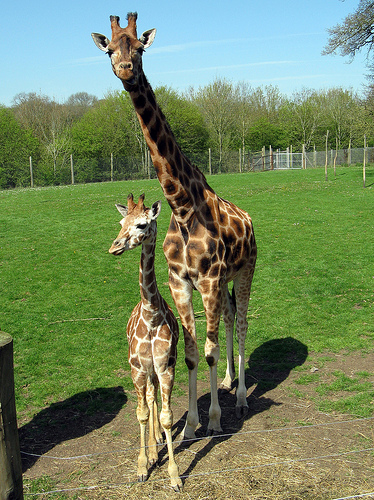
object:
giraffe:
[90, 11, 257, 446]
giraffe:
[108, 193, 178, 496]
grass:
[0, 188, 374, 499]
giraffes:
[90, 8, 258, 494]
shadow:
[149, 336, 308, 485]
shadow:
[15, 385, 127, 473]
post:
[29, 156, 34, 188]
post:
[70, 154, 75, 184]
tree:
[0, 106, 43, 189]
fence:
[29, 129, 374, 188]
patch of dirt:
[0, 336, 374, 500]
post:
[111, 151, 114, 181]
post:
[148, 150, 152, 179]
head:
[91, 10, 156, 87]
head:
[108, 192, 161, 256]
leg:
[235, 285, 250, 398]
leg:
[221, 292, 237, 381]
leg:
[168, 286, 200, 412]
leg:
[204, 295, 221, 422]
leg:
[146, 385, 157, 450]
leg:
[136, 380, 150, 465]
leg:
[159, 375, 178, 479]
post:
[209, 148, 213, 175]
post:
[239, 147, 242, 173]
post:
[287, 147, 290, 168]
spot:
[133, 95, 147, 110]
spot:
[147, 88, 157, 111]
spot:
[140, 105, 155, 126]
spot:
[158, 107, 166, 122]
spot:
[149, 115, 163, 144]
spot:
[157, 134, 167, 159]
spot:
[167, 137, 174, 155]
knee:
[204, 339, 220, 367]